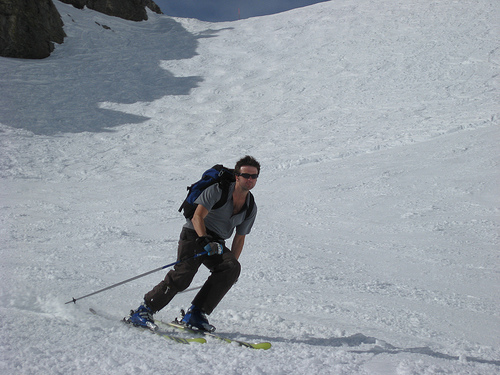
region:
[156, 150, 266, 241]
The man is carrying a backpack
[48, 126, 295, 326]
the man is skiing in the snow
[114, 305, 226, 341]
The man is wearing blue ski boots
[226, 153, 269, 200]
The man is wearing goggle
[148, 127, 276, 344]
the man is standing in the snow.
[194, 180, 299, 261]
The shirt is gray.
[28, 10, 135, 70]
The big rocks are in the snow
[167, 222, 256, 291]
The man has on gloves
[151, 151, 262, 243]
The backpack is blue and black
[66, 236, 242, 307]
The man is holding the ski pole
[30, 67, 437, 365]
person skiing down slope.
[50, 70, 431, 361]
person skiing down snowy slope.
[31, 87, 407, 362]
person skiing down snow hill.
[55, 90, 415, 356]
person skiing down snowy slope during daytime.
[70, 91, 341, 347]
man skiing down a snowy slope.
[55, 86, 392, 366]
man skiing down a snow hill.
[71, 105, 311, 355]
man skiing down slope during the day.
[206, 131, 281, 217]
man wearing dark shades.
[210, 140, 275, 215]
man with dark colored hair.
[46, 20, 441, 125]
patch of beautiful snow slope.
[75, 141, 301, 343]
man skiing on beautiful white snow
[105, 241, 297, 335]
man wearing winter pants while skiing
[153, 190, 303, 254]
man wearing short sleeve pullover while skiing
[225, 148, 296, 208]
man wearing dark color sun glasses while skiing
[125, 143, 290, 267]
man wearing a large back pack while he is skiing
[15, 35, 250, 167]
shadows of green pine trees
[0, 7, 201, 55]
bottom part of green pine trees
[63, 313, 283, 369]
yellow snow ski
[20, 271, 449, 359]
ski tracts on the snow slope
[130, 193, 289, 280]
two arms of a snow skier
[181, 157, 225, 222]
The man is wearing a backpack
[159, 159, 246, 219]
The man is wearing a blue backpack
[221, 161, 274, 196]
The man is wearing goggles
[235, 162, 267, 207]
The man is wearing black goggles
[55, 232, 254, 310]
The man is skiing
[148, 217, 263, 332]
The man is wearing pants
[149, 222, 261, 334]
The man is wearing grey pants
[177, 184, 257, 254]
The man is wearing a shirt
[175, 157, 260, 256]
The man is wearing a grey shirt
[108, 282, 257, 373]
The man is wearing shoes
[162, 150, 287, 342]
man is skiing through snow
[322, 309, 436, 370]
a white snow on the ground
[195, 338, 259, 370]
a white snow on the ground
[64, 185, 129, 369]
a white snow on the ground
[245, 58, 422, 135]
a white snow on the ground